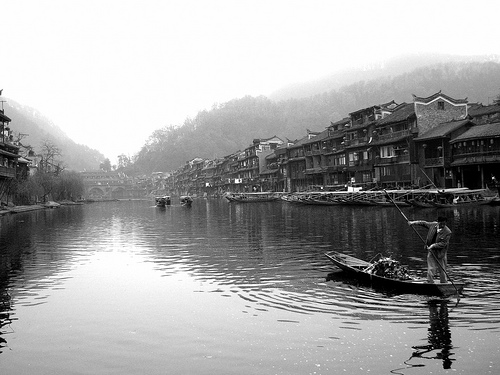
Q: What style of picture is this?
A: Black and white.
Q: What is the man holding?
A: An oar.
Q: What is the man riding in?
A: A boat.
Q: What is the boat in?
A: Water.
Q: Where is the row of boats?
A: On the right next to the buildings.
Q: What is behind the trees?
A: Mountains.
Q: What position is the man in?
A: Standing up.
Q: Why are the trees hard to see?
A: It's foggy.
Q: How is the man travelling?
A: In a boat.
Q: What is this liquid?
A: Water.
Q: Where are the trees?
A: Behind the rows of houses.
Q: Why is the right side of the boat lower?
A: The man's weight is holding it down.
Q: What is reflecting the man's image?
A: The water.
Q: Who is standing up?
A: The man on the boat.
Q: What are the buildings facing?
A: The waterway.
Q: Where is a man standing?
A: On a boat.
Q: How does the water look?
A: Calm.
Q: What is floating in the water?
A: Boats.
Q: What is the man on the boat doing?
A: Steering the boat.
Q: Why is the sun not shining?
A: It's too cloudy.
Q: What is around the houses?
A: There are mountains behind the houses.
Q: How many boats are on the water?
A: 1 boat.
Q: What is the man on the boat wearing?
A: A blazer and pants.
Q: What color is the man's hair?
A: His hair is black.